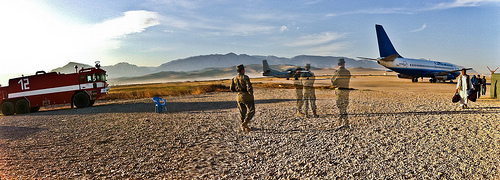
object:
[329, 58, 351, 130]
ghost soldiers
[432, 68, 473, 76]
wing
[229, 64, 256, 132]
jumpsuit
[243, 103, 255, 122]
leg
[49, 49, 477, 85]
mountain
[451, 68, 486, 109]
group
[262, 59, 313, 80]
airplane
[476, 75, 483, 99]
people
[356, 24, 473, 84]
airplane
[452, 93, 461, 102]
suitcase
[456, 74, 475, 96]
thawb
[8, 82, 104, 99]
white stripe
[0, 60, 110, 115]
fire truck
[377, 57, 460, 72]
white body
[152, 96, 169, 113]
chair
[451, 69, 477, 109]
man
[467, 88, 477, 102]
bag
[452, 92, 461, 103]
bag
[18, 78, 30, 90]
number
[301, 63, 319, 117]
jumpsuit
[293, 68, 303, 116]
jumpsuit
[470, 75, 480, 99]
people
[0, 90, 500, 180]
gravel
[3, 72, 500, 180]
ground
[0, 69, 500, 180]
airstrip